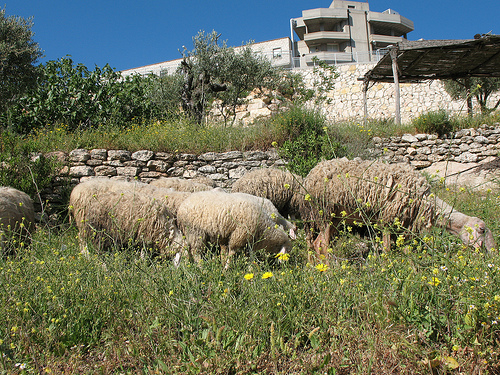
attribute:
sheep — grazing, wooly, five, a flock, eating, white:
[176, 189, 300, 272]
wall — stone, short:
[2, 123, 499, 222]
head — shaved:
[456, 211, 494, 255]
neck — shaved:
[431, 192, 467, 242]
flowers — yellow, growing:
[260, 273, 274, 281]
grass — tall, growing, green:
[4, 231, 499, 373]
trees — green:
[182, 28, 270, 129]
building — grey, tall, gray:
[86, 1, 415, 84]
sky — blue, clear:
[3, 2, 498, 78]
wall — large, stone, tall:
[207, 62, 497, 130]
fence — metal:
[273, 52, 386, 64]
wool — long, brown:
[298, 158, 436, 233]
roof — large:
[362, 35, 498, 85]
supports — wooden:
[389, 46, 402, 131]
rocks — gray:
[133, 149, 154, 163]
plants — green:
[264, 274, 281, 359]